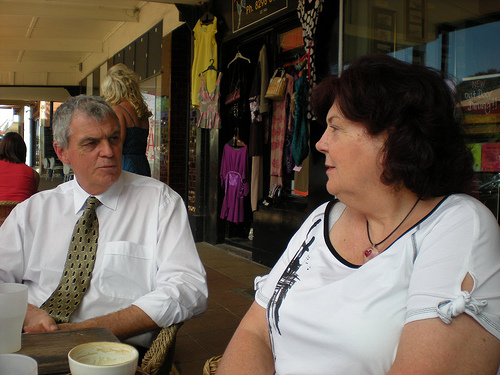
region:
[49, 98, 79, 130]
Man has grey hair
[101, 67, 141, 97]
Woman has blonde hair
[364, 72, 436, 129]
Woman has black hair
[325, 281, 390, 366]
Woman wearing white shirt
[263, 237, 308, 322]
Black design on shirt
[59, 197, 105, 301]
Man wearing teal green tie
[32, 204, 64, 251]
Man wearing white dress shirt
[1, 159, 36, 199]
Woman wearing red shirt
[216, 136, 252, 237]
Purple shirt hanging on hanger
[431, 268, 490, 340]
Bowtie in white shirt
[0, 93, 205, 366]
a man sitting in a wicker chair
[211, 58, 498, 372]
a woman sitting in a chair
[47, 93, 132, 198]
a grey haired man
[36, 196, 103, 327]
a spotted olive tie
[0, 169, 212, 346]
a man's white dress shirt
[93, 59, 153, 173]
a woman with long blonde hair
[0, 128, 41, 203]
a woman with red blouse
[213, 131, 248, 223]
a purple top hanging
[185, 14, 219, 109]
a yellow dress hanging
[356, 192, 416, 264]
a pendant necklace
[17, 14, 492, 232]
man and woman are talking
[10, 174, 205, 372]
man's shirt is white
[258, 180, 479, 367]
woman's shirt is white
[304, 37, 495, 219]
woman's hair is brown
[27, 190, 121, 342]
man's tie is gold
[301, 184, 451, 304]
woman's necklace is black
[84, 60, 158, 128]
woman's hair is blonde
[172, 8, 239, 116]
the dress is yellow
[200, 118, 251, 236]
the dress is purple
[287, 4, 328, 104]
the dress is polka dot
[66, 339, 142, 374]
round white used coffee cup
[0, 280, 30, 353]
large white coffee cup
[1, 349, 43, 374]
round white coffee cup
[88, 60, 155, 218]
blonde woman wearing a blue dress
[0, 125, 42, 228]
person in red shirt sitting at a table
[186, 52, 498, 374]
woman with black hair wearing a white shirt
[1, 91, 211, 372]
man with gray hair wearing a white shirt and gold tie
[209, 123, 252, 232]
purple dress hanging in shop window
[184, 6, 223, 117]
yellow dress hanging in shop window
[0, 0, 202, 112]
beige roof over sidewalk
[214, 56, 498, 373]
a woman in a white blouse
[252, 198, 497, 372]
a woman's white shirt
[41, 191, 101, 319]
a man's neck tie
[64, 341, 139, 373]
an empty coffee cup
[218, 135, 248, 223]
a purple dress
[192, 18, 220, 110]
a yellow dress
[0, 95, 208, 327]
a man wearing a neck tie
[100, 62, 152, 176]
a blonde haired woman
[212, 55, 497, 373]
a brunette haired woman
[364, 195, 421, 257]
a woman's necklace